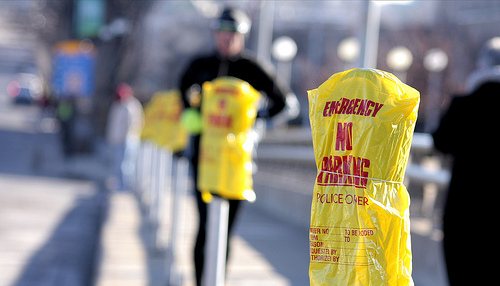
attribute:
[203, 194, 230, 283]
pole — metal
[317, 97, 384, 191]
words — red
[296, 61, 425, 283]
bag — yellow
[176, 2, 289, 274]
woman — running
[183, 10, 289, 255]
man — jogging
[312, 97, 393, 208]
writing — red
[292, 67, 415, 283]
cover — yellow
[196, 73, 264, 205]
cover — yellow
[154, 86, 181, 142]
cover — yellow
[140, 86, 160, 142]
cover — yellow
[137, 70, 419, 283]
meters — parking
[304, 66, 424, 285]
plastic — yellow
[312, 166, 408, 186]
string — white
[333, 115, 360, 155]
no — red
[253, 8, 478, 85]
lights — blurry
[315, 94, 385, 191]
word — red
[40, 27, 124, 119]
sign — blurry, blue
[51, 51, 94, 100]
sign — blue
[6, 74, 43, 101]
car — driving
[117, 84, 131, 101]
cap — red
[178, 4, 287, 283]
police officer — standing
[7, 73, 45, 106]
car — blurry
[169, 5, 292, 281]
woman — running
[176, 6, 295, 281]
man — jogging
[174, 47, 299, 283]
uniform — black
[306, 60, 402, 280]
bag — plastic, yellow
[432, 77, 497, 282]
coat — black